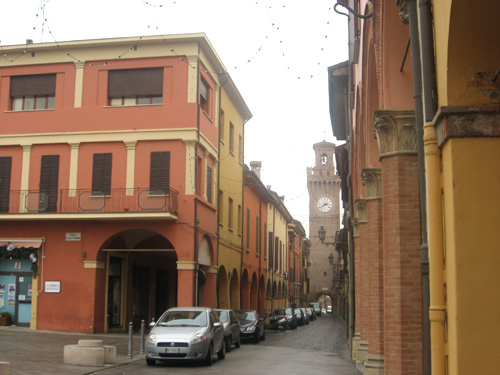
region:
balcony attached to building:
[0, 187, 180, 228]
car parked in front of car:
[144, 306, 227, 367]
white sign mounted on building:
[45, 281, 60, 293]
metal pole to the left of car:
[127, 321, 134, 358]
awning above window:
[0, 237, 42, 250]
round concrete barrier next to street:
[61, 338, 117, 367]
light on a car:
[185, 331, 212, 351]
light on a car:
[140, 325, 157, 348]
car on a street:
[270, 302, 300, 332]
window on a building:
[140, 141, 180, 191]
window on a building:
[107, 65, 170, 105]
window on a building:
[5, 62, 65, 112]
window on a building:
[218, 191, 240, 238]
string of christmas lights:
[10, 0, 358, 84]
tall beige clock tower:
[305, 130, 343, 302]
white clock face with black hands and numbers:
[315, 191, 335, 215]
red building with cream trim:
[5, 30, 229, 341]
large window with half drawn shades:
[5, 67, 65, 117]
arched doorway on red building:
[87, 221, 179, 339]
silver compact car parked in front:
[142, 297, 224, 369]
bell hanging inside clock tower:
[315, 150, 330, 167]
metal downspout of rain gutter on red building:
[212, 67, 226, 279]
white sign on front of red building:
[42, 273, 63, 297]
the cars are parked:
[161, 295, 328, 329]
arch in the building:
[87, 228, 196, 330]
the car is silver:
[148, 307, 218, 371]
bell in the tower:
[318, 155, 334, 181]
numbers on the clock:
[317, 195, 333, 213]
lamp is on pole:
[315, 225, 343, 247]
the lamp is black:
[317, 229, 331, 244]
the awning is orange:
[2, 240, 44, 248]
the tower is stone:
[307, 145, 345, 292]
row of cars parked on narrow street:
[142, 290, 322, 367]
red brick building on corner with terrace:
[5, 22, 220, 333]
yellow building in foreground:
[403, 0, 498, 369]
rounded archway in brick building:
[91, 233, 176, 330]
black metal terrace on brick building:
[3, 188, 183, 215]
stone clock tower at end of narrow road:
[306, 138, 343, 307]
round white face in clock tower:
[316, 192, 334, 215]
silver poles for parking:
[124, 319, 157, 359]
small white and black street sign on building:
[61, 230, 85, 244]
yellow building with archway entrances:
[218, 70, 263, 307]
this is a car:
[137, 285, 234, 361]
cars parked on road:
[139, 259, 325, 367]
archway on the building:
[74, 212, 194, 352]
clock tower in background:
[289, 112, 346, 308]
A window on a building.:
[141, 142, 181, 214]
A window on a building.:
[4, 61, 61, 115]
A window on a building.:
[241, 207, 253, 254]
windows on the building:
[12, 128, 206, 238]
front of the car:
[136, 302, 217, 369]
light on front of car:
[181, 324, 216, 351]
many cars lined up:
[142, 275, 344, 373]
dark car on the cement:
[222, 292, 278, 353]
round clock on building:
[286, 183, 348, 238]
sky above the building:
[246, 22, 329, 143]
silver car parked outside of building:
[138, 301, 228, 372]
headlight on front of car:
[186, 330, 211, 348]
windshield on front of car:
[151, 307, 209, 329]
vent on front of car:
[156, 337, 191, 351]